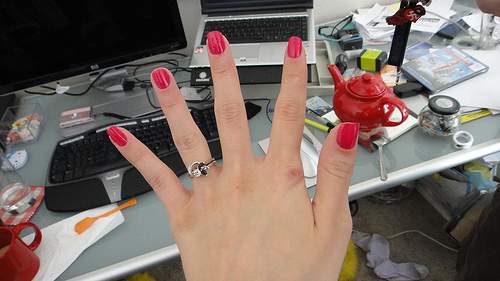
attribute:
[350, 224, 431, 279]
sock — white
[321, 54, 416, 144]
kettle — red, porcelain, a tea kettle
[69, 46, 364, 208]
fingernails — pink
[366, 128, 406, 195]
spoon — silver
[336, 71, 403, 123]
kettle — Red 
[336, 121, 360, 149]
nail — pink, polished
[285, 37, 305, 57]
nail — polished, pink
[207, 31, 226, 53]
nail — polished, pink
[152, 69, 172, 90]
nail — polished, pink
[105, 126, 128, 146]
nail — polished, pink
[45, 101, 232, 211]
keyboard — a computer keyboard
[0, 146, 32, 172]
note pad — a Hello Kitty item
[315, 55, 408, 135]
teapot — red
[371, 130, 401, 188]
spoon — silverboard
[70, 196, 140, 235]
utensil — orange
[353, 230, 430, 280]
socks — white, dirty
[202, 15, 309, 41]
keys — black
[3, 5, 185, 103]
monitor — black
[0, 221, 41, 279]
cup — Red 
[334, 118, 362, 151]
nails — Red 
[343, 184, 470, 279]
floor — carpeted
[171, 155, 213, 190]
ring — black 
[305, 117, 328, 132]
pen — yellow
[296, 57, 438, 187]
teapot — red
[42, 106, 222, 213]
keyboard — black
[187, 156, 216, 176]
ring — silver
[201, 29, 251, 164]
finger — long